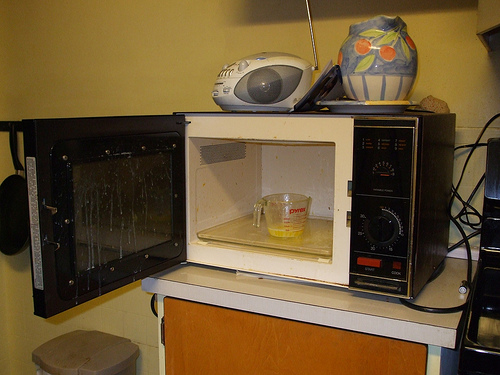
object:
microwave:
[18, 111, 456, 321]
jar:
[338, 14, 419, 102]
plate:
[314, 100, 422, 115]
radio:
[211, 0, 319, 114]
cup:
[253, 192, 311, 238]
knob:
[367, 215, 395, 243]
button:
[357, 256, 382, 267]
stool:
[30, 329, 141, 374]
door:
[21, 114, 187, 319]